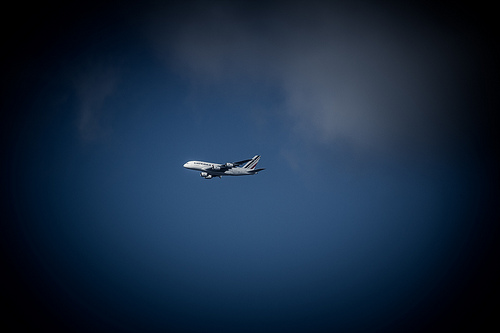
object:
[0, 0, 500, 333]
cloud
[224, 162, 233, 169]
airplane engines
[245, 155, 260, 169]
stripes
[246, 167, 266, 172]
tail fin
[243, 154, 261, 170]
wing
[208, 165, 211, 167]
windows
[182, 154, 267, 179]
airplane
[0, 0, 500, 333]
sky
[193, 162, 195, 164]
windows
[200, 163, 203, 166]
lateral windows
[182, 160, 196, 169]
cockpit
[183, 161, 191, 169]
nose